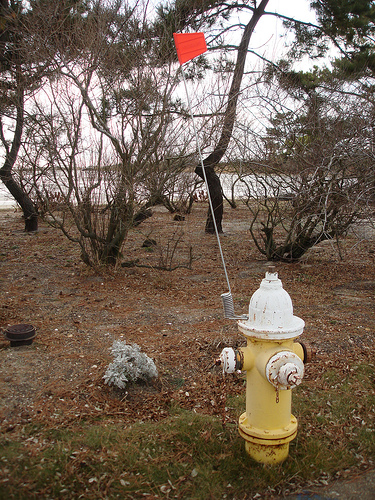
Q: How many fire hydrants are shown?
A: One.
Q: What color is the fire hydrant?
A: Yellow and white.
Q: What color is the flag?
A: Red.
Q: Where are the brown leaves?
A: Ground.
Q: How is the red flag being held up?
A: Metal pole.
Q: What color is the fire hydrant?
A: Yellow.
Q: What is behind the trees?
A: Water.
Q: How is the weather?
A: Overcast.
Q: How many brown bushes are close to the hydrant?
A: 2.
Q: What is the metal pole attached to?
A: The hydrant.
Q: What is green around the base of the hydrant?
A: Grass.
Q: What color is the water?
A: Grey.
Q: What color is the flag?
A: Red.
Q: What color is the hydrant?
A: Yellow.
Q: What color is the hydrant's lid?
A: White.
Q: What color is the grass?
A: Green.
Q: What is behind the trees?
A: Water.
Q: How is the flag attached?
A: With a pole.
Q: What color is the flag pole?
A: Silver.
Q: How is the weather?
A: Clear.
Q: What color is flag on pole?
A: Red.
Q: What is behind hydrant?
A: Trees.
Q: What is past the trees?
A: Body of water.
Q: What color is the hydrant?
A: Yellow.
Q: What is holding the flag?
A: A pole.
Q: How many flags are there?
A: One.